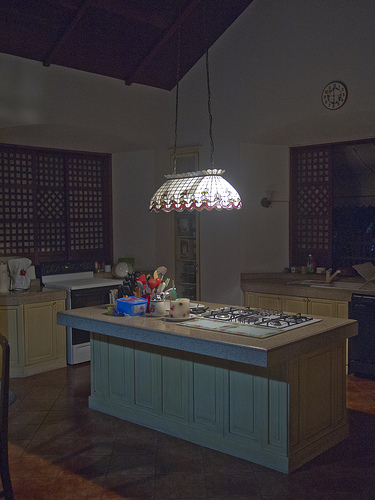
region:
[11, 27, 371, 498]
a kitchen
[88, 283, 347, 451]
a kitchen island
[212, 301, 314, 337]
a set of four burners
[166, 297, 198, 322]
a decorative candle on a plate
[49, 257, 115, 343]
a white stove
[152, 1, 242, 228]
a lamp hanging from the ceiling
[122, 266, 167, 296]
an assortment of kitchen utensils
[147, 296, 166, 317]
a small decorative pot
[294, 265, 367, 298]
a kitchen sink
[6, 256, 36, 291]
decorative white cloth napkins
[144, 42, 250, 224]
Light fixture hanging from ceiling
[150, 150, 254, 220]
Hanging light fixture is red and white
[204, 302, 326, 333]
Counter top range is off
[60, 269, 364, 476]
Kitchen with work island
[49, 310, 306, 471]
Kitchen island is blue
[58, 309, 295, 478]
Kitchen island is wood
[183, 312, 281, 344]
Insulated mats for hot pans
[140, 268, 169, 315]
Caddy full of kitchen utensils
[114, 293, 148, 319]
Blue box sitting on counter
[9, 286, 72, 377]
Kitchen cabinet has yellow door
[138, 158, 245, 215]
oblong overheas Tiffany style light fixture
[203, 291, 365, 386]
range top on a kitchen island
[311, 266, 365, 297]
sink with a corner faucet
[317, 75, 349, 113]
red rimmed whitefaced wall clock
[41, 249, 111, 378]
a automatic dishwasher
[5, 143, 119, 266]
red latticed wall area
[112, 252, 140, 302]
a block of black handled knives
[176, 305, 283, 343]
glass counter savers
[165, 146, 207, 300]
glassed door storage cupboard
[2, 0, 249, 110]
woof finished wood ceiling with exposed beams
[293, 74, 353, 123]
A kitchen clock on the wall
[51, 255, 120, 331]
The kitchen oven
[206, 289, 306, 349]
The kitchen stove top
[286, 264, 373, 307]
The kitchen sink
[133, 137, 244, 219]
Kitchen lighting over the island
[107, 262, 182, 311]
Various kitchen utensils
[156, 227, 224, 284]
Looks like pots and pans storage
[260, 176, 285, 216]
a wall light for the sink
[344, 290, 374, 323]
The kitchen dishwasher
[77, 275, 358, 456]
Prep and stove top island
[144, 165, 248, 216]
decorative light cover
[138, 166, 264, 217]
bright source of light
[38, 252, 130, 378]
oven with a digital clock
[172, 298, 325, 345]
island stove with gas burners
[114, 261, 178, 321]
lot of cooking utensils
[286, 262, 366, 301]
white kitchen sink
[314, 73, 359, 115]
red and white clock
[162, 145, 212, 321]
open kitchen pantry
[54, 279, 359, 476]
wood kitchen island counter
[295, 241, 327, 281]
bottle of dish soap